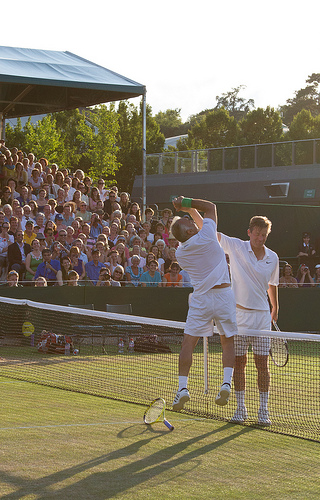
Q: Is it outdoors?
A: Yes, it is outdoors.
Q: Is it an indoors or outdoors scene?
A: It is outdoors.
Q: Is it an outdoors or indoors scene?
A: It is outdoors.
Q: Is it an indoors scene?
A: No, it is outdoors.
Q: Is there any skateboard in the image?
A: No, there are no skateboards.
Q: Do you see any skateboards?
A: No, there are no skateboards.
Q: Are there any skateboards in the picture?
A: No, there are no skateboards.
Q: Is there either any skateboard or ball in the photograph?
A: No, there are no skateboards or balls.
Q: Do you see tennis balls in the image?
A: No, there are no tennis balls.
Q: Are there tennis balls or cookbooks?
A: No, there are no tennis balls or cookbooks.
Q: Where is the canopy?
A: The canopy is at the match.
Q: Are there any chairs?
A: Yes, there is a chair.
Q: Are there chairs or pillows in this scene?
A: Yes, there is a chair.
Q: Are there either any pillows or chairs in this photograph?
A: Yes, there is a chair.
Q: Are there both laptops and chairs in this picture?
A: No, there is a chair but no laptops.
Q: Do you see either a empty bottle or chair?
A: Yes, there is an empty chair.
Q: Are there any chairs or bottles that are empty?
A: Yes, the chair is empty.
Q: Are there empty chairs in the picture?
A: Yes, there is an empty chair.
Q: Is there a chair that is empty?
A: Yes, there is a chair that is empty.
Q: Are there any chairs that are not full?
A: Yes, there is a empty chair.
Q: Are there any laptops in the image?
A: No, there are no laptops.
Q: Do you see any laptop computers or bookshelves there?
A: No, there are no laptop computers or bookshelves.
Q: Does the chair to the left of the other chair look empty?
A: Yes, the chair is empty.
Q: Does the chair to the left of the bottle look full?
A: No, the chair is empty.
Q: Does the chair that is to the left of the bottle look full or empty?
A: The chair is empty.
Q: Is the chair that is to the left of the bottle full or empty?
A: The chair is empty.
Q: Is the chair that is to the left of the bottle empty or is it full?
A: The chair is empty.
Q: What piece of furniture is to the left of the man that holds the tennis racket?
A: The piece of furniture is a chair.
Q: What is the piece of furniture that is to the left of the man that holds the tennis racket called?
A: The piece of furniture is a chair.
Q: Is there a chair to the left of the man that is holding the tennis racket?
A: Yes, there is a chair to the left of the man.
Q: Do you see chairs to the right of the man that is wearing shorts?
A: No, the chair is to the left of the man.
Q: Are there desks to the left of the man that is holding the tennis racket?
A: No, there is a chair to the left of the man.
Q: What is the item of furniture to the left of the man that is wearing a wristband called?
A: The piece of furniture is a chair.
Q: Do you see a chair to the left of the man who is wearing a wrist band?
A: Yes, there is a chair to the left of the man.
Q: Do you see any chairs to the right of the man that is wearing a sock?
A: No, the chair is to the left of the man.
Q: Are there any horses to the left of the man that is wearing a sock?
A: No, there is a chair to the left of the man.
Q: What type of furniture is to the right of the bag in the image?
A: The piece of furniture is a chair.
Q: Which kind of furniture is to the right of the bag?
A: The piece of furniture is a chair.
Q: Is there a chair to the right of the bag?
A: Yes, there is a chair to the right of the bag.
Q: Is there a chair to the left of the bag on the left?
A: No, the chair is to the right of the bag.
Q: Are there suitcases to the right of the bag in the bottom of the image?
A: No, there is a chair to the right of the bag.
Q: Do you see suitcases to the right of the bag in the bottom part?
A: No, there is a chair to the right of the bag.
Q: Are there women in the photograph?
A: Yes, there is a woman.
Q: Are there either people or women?
A: Yes, there is a woman.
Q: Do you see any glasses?
A: No, there are no glasses.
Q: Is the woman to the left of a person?
A: Yes, the woman is to the left of a person.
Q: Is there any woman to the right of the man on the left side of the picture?
A: Yes, there is a woman to the right of the man.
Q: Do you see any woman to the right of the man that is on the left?
A: Yes, there is a woman to the right of the man.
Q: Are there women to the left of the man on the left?
A: No, the woman is to the right of the man.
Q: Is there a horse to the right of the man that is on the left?
A: No, there is a woman to the right of the man.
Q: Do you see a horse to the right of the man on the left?
A: No, there is a woman to the right of the man.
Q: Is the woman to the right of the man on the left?
A: Yes, the woman is to the right of the man.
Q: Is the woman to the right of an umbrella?
A: No, the woman is to the right of the man.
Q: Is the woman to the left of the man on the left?
A: No, the woman is to the right of the man.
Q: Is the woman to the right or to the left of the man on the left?
A: The woman is to the right of the man.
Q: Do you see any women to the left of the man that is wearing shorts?
A: Yes, there is a woman to the left of the man.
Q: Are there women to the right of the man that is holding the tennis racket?
A: No, the woman is to the left of the man.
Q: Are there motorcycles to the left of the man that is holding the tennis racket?
A: No, there is a woman to the left of the man.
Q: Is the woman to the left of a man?
A: Yes, the woman is to the left of a man.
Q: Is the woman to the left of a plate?
A: No, the woman is to the left of a man.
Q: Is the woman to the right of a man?
A: No, the woman is to the left of a man.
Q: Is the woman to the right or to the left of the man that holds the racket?
A: The woman is to the left of the man.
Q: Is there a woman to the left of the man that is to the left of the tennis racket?
A: Yes, there is a woman to the left of the man.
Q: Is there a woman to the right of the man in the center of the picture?
A: No, the woman is to the left of the man.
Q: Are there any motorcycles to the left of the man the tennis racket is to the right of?
A: No, there is a woman to the left of the man.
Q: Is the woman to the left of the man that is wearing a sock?
A: Yes, the woman is to the left of the man.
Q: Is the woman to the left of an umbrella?
A: No, the woman is to the left of the man.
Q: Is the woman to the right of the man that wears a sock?
A: No, the woman is to the left of the man.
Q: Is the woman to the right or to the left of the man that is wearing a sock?
A: The woman is to the left of the man.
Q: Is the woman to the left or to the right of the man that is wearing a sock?
A: The woman is to the left of the man.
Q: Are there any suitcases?
A: No, there are no suitcases.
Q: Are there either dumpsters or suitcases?
A: No, there are no suitcases or dumpsters.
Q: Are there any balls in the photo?
A: No, there are no balls.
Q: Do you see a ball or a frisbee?
A: No, there are no balls or frisbees.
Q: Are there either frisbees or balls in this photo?
A: No, there are no balls or frisbees.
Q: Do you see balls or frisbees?
A: No, there are no balls or frisbees.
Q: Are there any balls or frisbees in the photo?
A: No, there are no balls or frisbees.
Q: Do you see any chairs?
A: Yes, there is a chair.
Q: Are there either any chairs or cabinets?
A: Yes, there is a chair.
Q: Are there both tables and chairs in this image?
A: No, there is a chair but no tables.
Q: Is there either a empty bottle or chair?
A: Yes, there is an empty chair.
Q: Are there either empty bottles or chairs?
A: Yes, there is an empty chair.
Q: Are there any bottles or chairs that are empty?
A: Yes, the chair is empty.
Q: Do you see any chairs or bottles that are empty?
A: Yes, the chair is empty.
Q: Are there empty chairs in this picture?
A: Yes, there is an empty chair.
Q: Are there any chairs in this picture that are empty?
A: Yes, there is a chair that is empty.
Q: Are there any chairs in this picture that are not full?
A: Yes, there is a empty chair.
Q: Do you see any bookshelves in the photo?
A: No, there are no bookshelves.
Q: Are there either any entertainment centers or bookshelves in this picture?
A: No, there are no bookshelves or entertainment centers.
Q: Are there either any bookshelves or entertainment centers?
A: No, there are no bookshelves or entertainment centers.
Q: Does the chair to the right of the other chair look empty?
A: Yes, the chair is empty.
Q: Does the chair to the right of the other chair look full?
A: No, the chair is empty.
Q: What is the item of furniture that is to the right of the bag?
A: The piece of furniture is a chair.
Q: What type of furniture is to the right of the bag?
A: The piece of furniture is a chair.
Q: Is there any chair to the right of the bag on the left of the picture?
A: Yes, there is a chair to the right of the bag.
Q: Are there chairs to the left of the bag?
A: No, the chair is to the right of the bag.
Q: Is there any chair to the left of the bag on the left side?
A: No, the chair is to the right of the bag.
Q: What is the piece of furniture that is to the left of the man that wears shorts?
A: The piece of furniture is a chair.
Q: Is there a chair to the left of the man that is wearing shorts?
A: Yes, there is a chair to the left of the man.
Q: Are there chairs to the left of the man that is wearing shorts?
A: Yes, there is a chair to the left of the man.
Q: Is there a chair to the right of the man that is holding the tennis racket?
A: No, the chair is to the left of the man.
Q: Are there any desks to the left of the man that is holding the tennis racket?
A: No, there is a chair to the left of the man.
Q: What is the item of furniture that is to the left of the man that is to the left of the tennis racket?
A: The piece of furniture is a chair.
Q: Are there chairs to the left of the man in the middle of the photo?
A: Yes, there is a chair to the left of the man.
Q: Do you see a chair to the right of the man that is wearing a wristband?
A: No, the chair is to the left of the man.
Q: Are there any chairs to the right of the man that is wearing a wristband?
A: No, the chair is to the left of the man.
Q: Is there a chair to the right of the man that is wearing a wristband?
A: No, the chair is to the left of the man.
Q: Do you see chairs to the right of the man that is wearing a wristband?
A: No, the chair is to the left of the man.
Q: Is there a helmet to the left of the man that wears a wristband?
A: No, there is a chair to the left of the man.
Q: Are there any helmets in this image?
A: No, there are no helmets.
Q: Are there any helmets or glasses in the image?
A: No, there are no helmets or glasses.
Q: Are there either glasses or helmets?
A: No, there are no helmets or glasses.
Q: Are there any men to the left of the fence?
A: Yes, there is a man to the left of the fence.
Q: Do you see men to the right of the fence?
A: No, the man is to the left of the fence.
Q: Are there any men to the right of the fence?
A: No, the man is to the left of the fence.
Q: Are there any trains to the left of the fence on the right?
A: No, there is a man to the left of the fence.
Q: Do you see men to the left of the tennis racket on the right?
A: Yes, there is a man to the left of the racket.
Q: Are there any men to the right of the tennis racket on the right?
A: No, the man is to the left of the tennis racket.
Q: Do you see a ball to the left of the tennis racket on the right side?
A: No, there is a man to the left of the racket.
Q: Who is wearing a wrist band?
A: The man is wearing a wrist band.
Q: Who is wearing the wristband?
A: The man is wearing a wrist band.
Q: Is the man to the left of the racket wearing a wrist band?
A: Yes, the man is wearing a wrist band.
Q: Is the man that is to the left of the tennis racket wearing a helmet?
A: No, the man is wearing a wrist band.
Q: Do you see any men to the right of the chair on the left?
A: Yes, there is a man to the right of the chair.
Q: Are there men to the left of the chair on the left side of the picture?
A: No, the man is to the right of the chair.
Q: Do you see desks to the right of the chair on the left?
A: No, there is a man to the right of the chair.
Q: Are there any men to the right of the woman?
A: Yes, there is a man to the right of the woman.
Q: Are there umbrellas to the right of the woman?
A: No, there is a man to the right of the woman.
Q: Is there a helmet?
A: No, there are no helmets.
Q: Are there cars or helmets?
A: No, there are no helmets or cars.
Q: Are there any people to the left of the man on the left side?
A: Yes, there is a person to the left of the man.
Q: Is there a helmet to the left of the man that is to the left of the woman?
A: No, there is a person to the left of the man.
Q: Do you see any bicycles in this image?
A: No, there are no bicycles.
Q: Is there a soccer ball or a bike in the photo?
A: No, there are no bikes or soccer balls.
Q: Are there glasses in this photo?
A: No, there are no glasses.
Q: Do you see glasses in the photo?
A: No, there are no glasses.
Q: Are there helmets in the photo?
A: No, there are no helmets.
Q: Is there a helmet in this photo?
A: No, there are no helmets.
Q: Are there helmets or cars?
A: No, there are no helmets or cars.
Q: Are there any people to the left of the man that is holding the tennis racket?
A: Yes, there is a person to the left of the man.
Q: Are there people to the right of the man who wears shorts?
A: No, the person is to the left of the man.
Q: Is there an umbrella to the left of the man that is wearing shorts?
A: No, there is a person to the left of the man.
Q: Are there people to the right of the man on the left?
A: Yes, there is a person to the right of the man.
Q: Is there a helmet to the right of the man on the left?
A: No, there is a person to the right of the man.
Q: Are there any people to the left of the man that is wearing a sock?
A: Yes, there is a person to the left of the man.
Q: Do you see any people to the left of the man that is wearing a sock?
A: Yes, there is a person to the left of the man.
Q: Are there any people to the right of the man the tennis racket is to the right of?
A: No, the person is to the left of the man.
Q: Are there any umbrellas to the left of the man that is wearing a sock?
A: No, there is a person to the left of the man.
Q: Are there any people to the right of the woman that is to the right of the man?
A: Yes, there is a person to the right of the woman.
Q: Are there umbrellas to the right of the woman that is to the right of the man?
A: No, there is a person to the right of the woman.